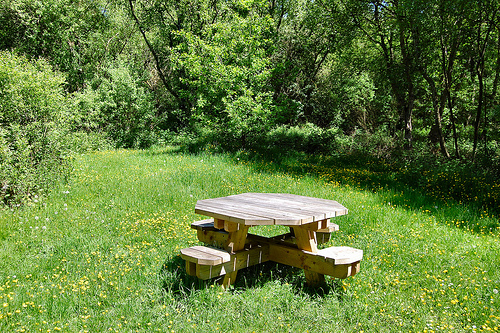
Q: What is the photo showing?
A: It is showing a forest.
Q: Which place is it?
A: It is a forest.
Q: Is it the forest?
A: Yes, it is the forest.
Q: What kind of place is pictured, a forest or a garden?
A: It is a forest.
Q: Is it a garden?
A: No, it is a forest.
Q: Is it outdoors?
A: Yes, it is outdoors.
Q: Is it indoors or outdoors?
A: It is outdoors.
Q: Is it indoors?
A: No, it is outdoors.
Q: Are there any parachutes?
A: No, there are no parachutes.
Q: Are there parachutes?
A: No, there are no parachutes.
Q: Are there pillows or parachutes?
A: No, there are no parachutes or pillows.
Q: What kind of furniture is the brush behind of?
A: The brush is behind the table.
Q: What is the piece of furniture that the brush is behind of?
A: The piece of furniture is a table.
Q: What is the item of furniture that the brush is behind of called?
A: The piece of furniture is a table.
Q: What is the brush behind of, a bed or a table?
A: The brush is behind a table.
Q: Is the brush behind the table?
A: Yes, the brush is behind the table.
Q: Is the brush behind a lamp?
A: No, the brush is behind the table.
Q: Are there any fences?
A: No, there are no fences.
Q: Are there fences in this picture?
A: No, there are no fences.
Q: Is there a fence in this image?
A: No, there are no fences.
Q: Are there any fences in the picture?
A: No, there are no fences.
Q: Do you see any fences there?
A: No, there are no fences.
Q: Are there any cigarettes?
A: No, there are no cigarettes.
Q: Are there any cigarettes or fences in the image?
A: No, there are no cigarettes or fences.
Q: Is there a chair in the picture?
A: Yes, there is a chair.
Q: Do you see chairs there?
A: Yes, there is a chair.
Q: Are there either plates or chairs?
A: Yes, there is a chair.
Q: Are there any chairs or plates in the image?
A: Yes, there is a chair.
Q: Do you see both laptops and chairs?
A: No, there is a chair but no laptops.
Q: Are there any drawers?
A: No, there are no drawers.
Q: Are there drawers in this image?
A: No, there are no drawers.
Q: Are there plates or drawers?
A: No, there are no drawers or plates.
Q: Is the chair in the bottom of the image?
A: Yes, the chair is in the bottom of the image.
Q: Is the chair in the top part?
A: No, the chair is in the bottom of the image.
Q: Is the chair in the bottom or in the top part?
A: The chair is in the bottom of the image.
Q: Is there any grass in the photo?
A: Yes, there is grass.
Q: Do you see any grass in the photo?
A: Yes, there is grass.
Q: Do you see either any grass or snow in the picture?
A: Yes, there is grass.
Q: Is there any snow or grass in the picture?
A: Yes, there is grass.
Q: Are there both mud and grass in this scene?
A: No, there is grass but no mud.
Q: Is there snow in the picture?
A: No, there is no snow.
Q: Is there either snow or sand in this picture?
A: No, there are no snow or sand.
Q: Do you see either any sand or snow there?
A: No, there are no snow or sand.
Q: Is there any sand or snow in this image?
A: No, there are no snow or sand.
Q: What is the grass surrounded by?
A: The grass is surrounded by the tree.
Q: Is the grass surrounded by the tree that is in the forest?
A: Yes, the grass is surrounded by the tree.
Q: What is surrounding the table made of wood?
A: The grass is surrounding the table.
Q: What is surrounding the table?
A: The grass is surrounding the table.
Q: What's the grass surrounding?
A: The grass is surrounding the table.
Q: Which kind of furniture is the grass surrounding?
A: The grass is surrounding the table.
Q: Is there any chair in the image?
A: Yes, there is a chair.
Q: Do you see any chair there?
A: Yes, there is a chair.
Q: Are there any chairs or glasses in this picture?
A: Yes, there is a chair.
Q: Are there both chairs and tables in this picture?
A: Yes, there are both a chair and a table.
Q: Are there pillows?
A: No, there are no pillows.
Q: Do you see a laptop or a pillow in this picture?
A: No, there are no pillows or laptops.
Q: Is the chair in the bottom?
A: Yes, the chair is in the bottom of the image.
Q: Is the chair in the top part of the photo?
A: No, the chair is in the bottom of the image.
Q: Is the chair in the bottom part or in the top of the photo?
A: The chair is in the bottom of the image.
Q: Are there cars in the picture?
A: No, there are no cars.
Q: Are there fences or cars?
A: No, there are no cars or fences.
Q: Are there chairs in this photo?
A: Yes, there is a chair.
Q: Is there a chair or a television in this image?
A: Yes, there is a chair.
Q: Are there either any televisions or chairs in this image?
A: Yes, there is a chair.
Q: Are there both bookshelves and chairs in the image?
A: No, there is a chair but no bookshelves.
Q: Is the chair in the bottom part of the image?
A: Yes, the chair is in the bottom of the image.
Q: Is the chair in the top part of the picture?
A: No, the chair is in the bottom of the image.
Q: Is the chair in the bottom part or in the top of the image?
A: The chair is in the bottom of the image.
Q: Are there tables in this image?
A: Yes, there is a table.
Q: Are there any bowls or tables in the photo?
A: Yes, there is a table.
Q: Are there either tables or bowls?
A: Yes, there is a table.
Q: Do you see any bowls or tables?
A: Yes, there is a table.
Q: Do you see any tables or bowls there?
A: Yes, there is a table.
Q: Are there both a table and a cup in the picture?
A: No, there is a table but no cups.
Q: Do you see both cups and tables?
A: No, there is a table but no cups.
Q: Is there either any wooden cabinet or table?
A: Yes, there is a wood table.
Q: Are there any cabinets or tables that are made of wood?
A: Yes, the table is made of wood.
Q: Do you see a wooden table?
A: Yes, there is a wood table.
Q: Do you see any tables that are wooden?
A: Yes, there is a table that is wooden.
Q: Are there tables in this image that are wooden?
A: Yes, there is a table that is wooden.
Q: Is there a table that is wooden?
A: Yes, there is a table that is wooden.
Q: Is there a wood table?
A: Yes, there is a table that is made of wood.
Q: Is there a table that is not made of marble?
A: Yes, there is a table that is made of wood.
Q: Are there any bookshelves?
A: No, there are no bookshelves.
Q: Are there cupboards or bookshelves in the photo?
A: No, there are no bookshelves or cupboards.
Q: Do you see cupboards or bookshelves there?
A: No, there are no bookshelves or cupboards.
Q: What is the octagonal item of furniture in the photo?
A: The piece of furniture is a table.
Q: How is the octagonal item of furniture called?
A: The piece of furniture is a table.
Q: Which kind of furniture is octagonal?
A: The furniture is a table.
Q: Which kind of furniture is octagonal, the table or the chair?
A: The table is octagonal.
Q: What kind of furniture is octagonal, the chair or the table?
A: The table is octagonal.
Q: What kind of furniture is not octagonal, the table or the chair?
A: The chair is not octagonal.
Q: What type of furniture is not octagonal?
A: The furniture is a chair.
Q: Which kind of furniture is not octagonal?
A: The furniture is a chair.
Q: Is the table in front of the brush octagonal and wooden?
A: Yes, the table is octagonal and wooden.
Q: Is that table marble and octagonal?
A: No, the table is octagonal but wooden.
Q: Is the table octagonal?
A: Yes, the table is octagonal.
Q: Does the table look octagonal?
A: Yes, the table is octagonal.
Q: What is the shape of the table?
A: The table is octagonal.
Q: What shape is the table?
A: The table is octagonal.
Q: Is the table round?
A: No, the table is octagonal.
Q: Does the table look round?
A: No, the table is octagonal.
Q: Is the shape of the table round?
A: No, the table is octagonal.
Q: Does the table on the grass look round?
A: No, the table is octagonal.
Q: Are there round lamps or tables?
A: No, there is a table but it is octagonal.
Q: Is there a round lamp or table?
A: No, there is a table but it is octagonal.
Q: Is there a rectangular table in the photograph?
A: No, there is a table but it is octagonal.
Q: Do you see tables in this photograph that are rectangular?
A: No, there is a table but it is octagonal.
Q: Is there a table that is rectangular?
A: No, there is a table but it is octagonal.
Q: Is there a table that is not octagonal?
A: No, there is a table but it is octagonal.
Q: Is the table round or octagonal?
A: The table is octagonal.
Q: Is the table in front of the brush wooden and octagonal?
A: Yes, the table is wooden and octagonal.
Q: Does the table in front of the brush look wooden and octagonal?
A: Yes, the table is wooden and octagonal.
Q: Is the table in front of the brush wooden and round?
A: No, the table is wooden but octagonal.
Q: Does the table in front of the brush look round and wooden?
A: No, the table is wooden but octagonal.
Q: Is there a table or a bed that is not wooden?
A: No, there is a table but it is wooden.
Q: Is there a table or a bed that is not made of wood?
A: No, there is a table but it is made of wood.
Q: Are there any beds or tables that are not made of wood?
A: No, there is a table but it is made of wood.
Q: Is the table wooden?
A: Yes, the table is wooden.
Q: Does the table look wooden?
A: Yes, the table is wooden.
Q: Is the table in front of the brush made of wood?
A: Yes, the table is made of wood.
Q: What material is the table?
A: The table is made of wood.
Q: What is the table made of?
A: The table is made of wood.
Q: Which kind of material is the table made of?
A: The table is made of wood.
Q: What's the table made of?
A: The table is made of wood.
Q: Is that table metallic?
A: No, the table is wooden.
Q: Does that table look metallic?
A: No, the table is wooden.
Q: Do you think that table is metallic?
A: No, the table is wooden.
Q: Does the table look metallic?
A: No, the table is wooden.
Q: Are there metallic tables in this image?
A: No, there is a table but it is wooden.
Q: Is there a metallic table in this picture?
A: No, there is a table but it is wooden.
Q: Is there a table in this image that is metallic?
A: No, there is a table but it is wooden.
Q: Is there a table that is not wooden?
A: No, there is a table but it is wooden.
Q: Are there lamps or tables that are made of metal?
A: No, there is a table but it is made of wood.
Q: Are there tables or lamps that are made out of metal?
A: No, there is a table but it is made of wood.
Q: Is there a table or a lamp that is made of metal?
A: No, there is a table but it is made of wood.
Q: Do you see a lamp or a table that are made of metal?
A: No, there is a table but it is made of wood.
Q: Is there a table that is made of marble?
A: No, there is a table but it is made of wood.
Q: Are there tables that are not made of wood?
A: No, there is a table but it is made of wood.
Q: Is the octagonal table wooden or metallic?
A: The table is wooden.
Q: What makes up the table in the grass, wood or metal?
A: The table is made of wood.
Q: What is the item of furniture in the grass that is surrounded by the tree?
A: The piece of furniture is a table.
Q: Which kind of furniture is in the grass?
A: The piece of furniture is a table.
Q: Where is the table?
A: The table is in the grass.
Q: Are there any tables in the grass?
A: Yes, there is a table in the grass.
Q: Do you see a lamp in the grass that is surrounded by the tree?
A: No, there is a table in the grass.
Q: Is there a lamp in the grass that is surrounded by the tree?
A: No, there is a table in the grass.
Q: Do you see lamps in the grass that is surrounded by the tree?
A: No, there is a table in the grass.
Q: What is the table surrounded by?
A: The table is surrounded by the grass.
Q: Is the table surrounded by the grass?
A: Yes, the table is surrounded by the grass.